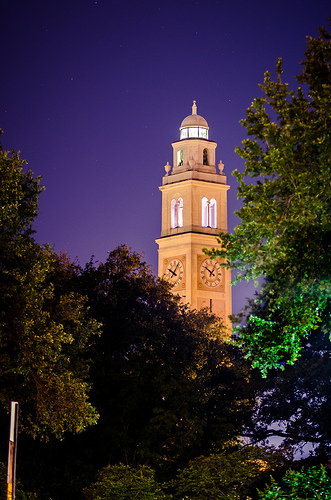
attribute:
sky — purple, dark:
[3, 3, 330, 345]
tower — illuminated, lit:
[139, 95, 247, 339]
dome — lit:
[170, 99, 215, 139]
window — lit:
[200, 193, 219, 228]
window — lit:
[170, 198, 185, 227]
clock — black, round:
[196, 259, 226, 288]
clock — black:
[161, 258, 186, 287]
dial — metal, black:
[206, 264, 215, 276]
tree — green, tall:
[220, 23, 331, 378]